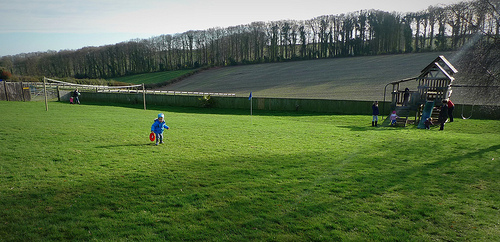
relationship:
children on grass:
[150, 112, 171, 146] [1, 98, 499, 241]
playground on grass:
[383, 54, 457, 129] [1, 98, 499, 241]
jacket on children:
[151, 118, 168, 135] [150, 112, 171, 146]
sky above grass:
[0, 0, 499, 47] [1, 98, 499, 241]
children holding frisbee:
[150, 112, 171, 146] [148, 131, 158, 142]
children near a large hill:
[70, 87, 454, 145] [91, 49, 498, 103]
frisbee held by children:
[148, 131, 158, 142] [150, 112, 171, 146]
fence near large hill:
[58, 79, 499, 120] [91, 49, 498, 103]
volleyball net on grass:
[42, 76, 148, 111] [1, 98, 499, 241]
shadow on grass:
[0, 99, 499, 241] [1, 98, 499, 241]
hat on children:
[156, 113, 164, 119] [150, 112, 171, 146]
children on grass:
[70, 87, 454, 145] [1, 98, 499, 241]